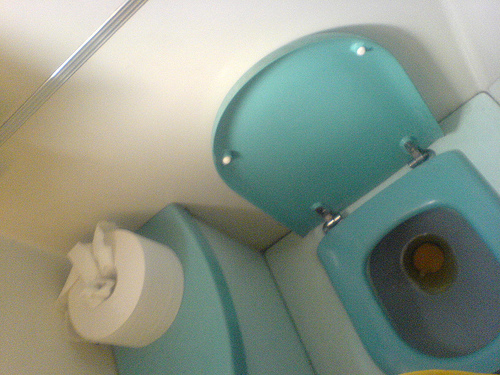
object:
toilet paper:
[58, 218, 182, 348]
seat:
[315, 148, 500, 374]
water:
[404, 235, 458, 296]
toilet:
[210, 32, 500, 374]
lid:
[210, 28, 445, 240]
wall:
[1, 246, 112, 375]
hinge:
[405, 142, 429, 168]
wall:
[0, 0, 500, 243]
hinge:
[316, 207, 342, 234]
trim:
[0, 0, 141, 145]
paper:
[58, 221, 115, 309]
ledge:
[110, 201, 248, 375]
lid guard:
[357, 47, 366, 56]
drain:
[403, 236, 456, 294]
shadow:
[312, 22, 463, 134]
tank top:
[111, 200, 248, 374]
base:
[261, 92, 500, 375]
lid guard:
[222, 156, 231, 165]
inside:
[364, 202, 499, 360]